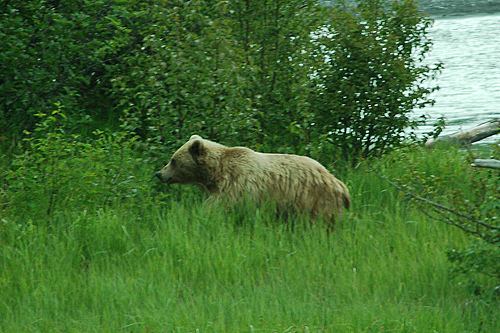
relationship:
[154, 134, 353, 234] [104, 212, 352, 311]
bear in grass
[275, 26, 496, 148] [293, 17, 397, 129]
water behind bushes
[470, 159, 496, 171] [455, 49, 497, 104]
tree trunk out of water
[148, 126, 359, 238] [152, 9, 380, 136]
bear front of bushes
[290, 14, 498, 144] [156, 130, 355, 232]
river behind bear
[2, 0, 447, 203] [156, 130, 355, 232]
bushes behind bear